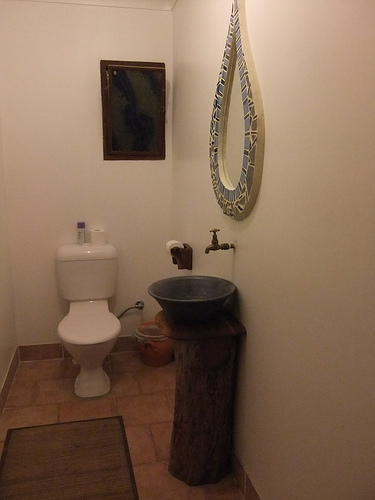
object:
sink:
[146, 273, 237, 328]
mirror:
[207, 0, 267, 223]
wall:
[168, 0, 375, 500]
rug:
[0, 412, 138, 498]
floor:
[0, 350, 245, 499]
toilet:
[54, 242, 122, 400]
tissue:
[89, 227, 106, 247]